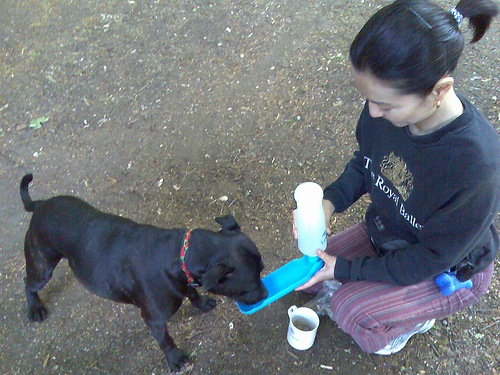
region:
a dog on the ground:
[36, 129, 354, 358]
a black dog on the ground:
[29, 133, 276, 364]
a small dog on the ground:
[19, 158, 184, 374]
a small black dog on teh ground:
[5, 151, 255, 367]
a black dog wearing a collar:
[11, 148, 390, 374]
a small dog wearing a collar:
[18, 78, 378, 361]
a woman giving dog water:
[97, 21, 449, 361]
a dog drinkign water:
[4, 153, 310, 344]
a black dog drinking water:
[60, 143, 349, 369]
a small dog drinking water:
[35, 159, 333, 367]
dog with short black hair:
[20, 173, 267, 369]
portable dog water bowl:
[237, 183, 325, 315]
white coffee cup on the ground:
[286, 305, 319, 348]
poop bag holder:
[435, 268, 472, 297]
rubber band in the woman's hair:
[447, 7, 462, 22]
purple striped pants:
[326, 225, 490, 352]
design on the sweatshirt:
[362, 153, 423, 232]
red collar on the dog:
[179, 230, 197, 285]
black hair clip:
[411, 5, 434, 29]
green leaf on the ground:
[27, 116, 49, 127]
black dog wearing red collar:
[11, 167, 294, 351]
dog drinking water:
[13, 160, 350, 340]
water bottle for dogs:
[223, 170, 330, 334]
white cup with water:
[275, 299, 322, 356]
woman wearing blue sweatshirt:
[282, 7, 484, 344]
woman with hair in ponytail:
[304, 8, 474, 338]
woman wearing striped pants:
[281, 2, 484, 349]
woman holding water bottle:
[275, 5, 482, 346]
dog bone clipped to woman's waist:
[431, 266, 478, 306]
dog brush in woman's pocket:
[452, 258, 475, 286]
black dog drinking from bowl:
[6, 162, 260, 371]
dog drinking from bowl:
[8, 165, 268, 368]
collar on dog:
[173, 225, 201, 288]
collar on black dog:
[171, 217, 205, 282]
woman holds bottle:
[282, 174, 333, 254]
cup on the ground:
[288, 305, 318, 349]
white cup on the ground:
[286, 306, 321, 351]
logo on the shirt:
[379, 152, 416, 211]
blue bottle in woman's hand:
[288, 180, 333, 255]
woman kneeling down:
[322, 1, 496, 349]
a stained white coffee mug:
[285, 300, 317, 350]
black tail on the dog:
[21, 173, 39, 208]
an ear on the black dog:
[215, 210, 235, 232]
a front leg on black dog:
[148, 308, 185, 373]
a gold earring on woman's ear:
[433, 78, 455, 108]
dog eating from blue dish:
[253, 290, 272, 302]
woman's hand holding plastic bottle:
[289, 176, 331, 255]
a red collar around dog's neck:
[182, 225, 192, 285]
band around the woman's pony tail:
[452, 0, 499, 42]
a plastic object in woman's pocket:
[440, 270, 472, 293]